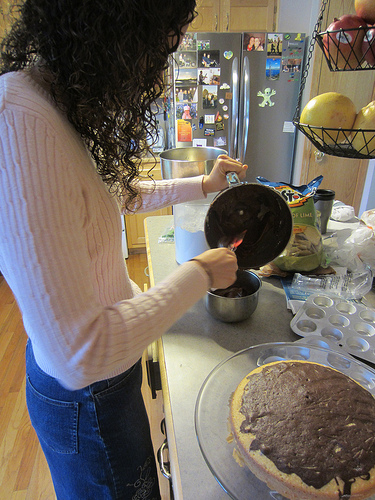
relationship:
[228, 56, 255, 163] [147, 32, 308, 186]
handle in front of refrigerator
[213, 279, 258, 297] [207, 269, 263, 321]
icing inside bowl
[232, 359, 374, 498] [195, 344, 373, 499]
cake on dish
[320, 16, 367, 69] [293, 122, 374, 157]
apple inside of basket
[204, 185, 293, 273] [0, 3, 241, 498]
frosting made by woman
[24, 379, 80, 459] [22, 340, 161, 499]
pocket behind jeans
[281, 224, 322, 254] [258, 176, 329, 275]
chips inside of bag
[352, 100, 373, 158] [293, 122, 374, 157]
grapefruit on top of basket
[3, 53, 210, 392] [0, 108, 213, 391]
sweater with sleeves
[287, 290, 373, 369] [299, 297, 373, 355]
pan with slots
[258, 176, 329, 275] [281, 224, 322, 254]
bag surrounding chips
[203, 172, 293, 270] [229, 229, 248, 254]
bowl surrounding spatula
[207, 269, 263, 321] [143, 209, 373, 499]
bowl on top of counter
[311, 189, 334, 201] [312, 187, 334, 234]
lid on cup